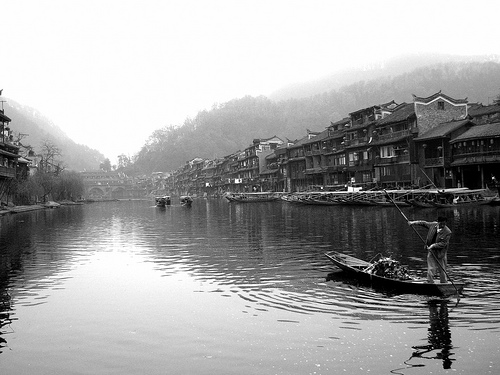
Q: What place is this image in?
A: It is at the river.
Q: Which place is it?
A: It is a river.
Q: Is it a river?
A: Yes, it is a river.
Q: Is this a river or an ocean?
A: It is a river.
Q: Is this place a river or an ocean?
A: It is a river.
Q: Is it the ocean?
A: No, it is the river.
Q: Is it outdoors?
A: Yes, it is outdoors.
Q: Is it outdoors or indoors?
A: It is outdoors.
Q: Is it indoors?
A: No, it is outdoors.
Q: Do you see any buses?
A: No, there are no buses.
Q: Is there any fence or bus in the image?
A: No, there are no buses or fences.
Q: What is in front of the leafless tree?
A: The buildings are in front of the tree.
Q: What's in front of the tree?
A: The buildings are in front of the tree.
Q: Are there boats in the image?
A: Yes, there is a boat.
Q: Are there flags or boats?
A: Yes, there is a boat.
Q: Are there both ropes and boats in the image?
A: No, there is a boat but no ropes.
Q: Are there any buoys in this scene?
A: No, there are no buoys.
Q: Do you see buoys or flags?
A: No, there are no buoys or flags.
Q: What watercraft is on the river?
A: The watercraft is a boat.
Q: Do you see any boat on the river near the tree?
A: Yes, there is a boat on the river.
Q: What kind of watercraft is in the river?
A: The watercraft is a boat.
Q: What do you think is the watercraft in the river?
A: The watercraft is a boat.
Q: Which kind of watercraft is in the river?
A: The watercraft is a boat.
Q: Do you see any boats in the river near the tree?
A: Yes, there is a boat in the river.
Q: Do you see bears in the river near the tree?
A: No, there is a boat in the river.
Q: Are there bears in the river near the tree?
A: No, there is a boat in the river.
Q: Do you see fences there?
A: No, there are no fences.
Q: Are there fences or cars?
A: No, there are no fences or cars.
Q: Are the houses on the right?
A: Yes, the houses are on the right of the image.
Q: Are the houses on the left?
A: No, the houses are on the right of the image.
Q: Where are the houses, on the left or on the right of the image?
A: The houses are on the right of the image.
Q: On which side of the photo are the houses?
A: The houses are on the right of the image.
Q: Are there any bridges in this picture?
A: Yes, there is a bridge.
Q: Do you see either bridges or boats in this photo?
A: Yes, there is a bridge.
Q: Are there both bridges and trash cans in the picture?
A: No, there is a bridge but no trash cans.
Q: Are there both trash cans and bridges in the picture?
A: No, there is a bridge but no trash cans.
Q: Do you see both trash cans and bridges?
A: No, there is a bridge but no trash cans.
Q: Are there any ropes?
A: No, there are no ropes.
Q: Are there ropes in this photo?
A: No, there are no ropes.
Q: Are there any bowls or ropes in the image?
A: No, there are no ropes or bowls.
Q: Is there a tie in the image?
A: No, there are no ties.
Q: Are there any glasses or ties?
A: No, there are no ties or glasses.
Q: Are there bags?
A: No, there are no bags.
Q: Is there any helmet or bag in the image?
A: No, there are no bags or helmets.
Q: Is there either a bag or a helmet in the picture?
A: No, there are no bags or helmets.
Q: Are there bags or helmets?
A: No, there are no bags or helmets.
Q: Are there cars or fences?
A: No, there are no fences or cars.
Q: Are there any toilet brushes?
A: No, there are no toilet brushes.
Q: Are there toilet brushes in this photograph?
A: No, there are no toilet brushes.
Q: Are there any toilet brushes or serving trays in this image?
A: No, there are no toilet brushes or serving trays.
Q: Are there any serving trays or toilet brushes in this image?
A: No, there are no toilet brushes or serving trays.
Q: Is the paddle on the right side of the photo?
A: Yes, the paddle is on the right of the image.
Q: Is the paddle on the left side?
A: No, the paddle is on the right of the image.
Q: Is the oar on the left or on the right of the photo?
A: The oar is on the right of the image.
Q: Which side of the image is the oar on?
A: The oar is on the right of the image.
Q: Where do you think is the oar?
A: The oar is in the river.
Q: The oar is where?
A: The oar is in the river.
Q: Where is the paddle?
A: The oar is in the river.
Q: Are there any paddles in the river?
A: Yes, there is a paddle in the river.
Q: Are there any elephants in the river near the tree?
A: No, there is a paddle in the river.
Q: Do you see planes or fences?
A: No, there are no fences or planes.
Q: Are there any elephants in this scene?
A: No, there are no elephants.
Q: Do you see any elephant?
A: No, there are no elephants.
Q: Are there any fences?
A: No, there are no fences.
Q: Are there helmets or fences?
A: No, there are no fences or helmets.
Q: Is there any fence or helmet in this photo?
A: No, there are no fences or helmets.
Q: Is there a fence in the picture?
A: No, there are no fences.